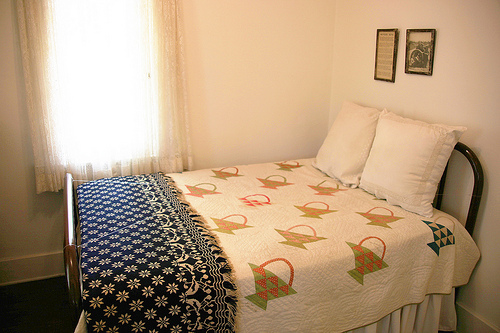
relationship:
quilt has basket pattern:
[163, 165, 463, 309] [270, 223, 334, 258]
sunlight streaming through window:
[48, 2, 152, 163] [8, 1, 198, 174]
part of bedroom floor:
[2, 260, 85, 325] [7, 269, 466, 332]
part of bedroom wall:
[189, 12, 307, 90] [6, 2, 328, 287]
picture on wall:
[401, 26, 432, 76] [333, 6, 498, 326]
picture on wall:
[368, 25, 399, 88] [333, 6, 498, 326]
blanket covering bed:
[65, 167, 227, 326] [57, 71, 478, 325]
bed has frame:
[57, 71, 478, 325] [340, 106, 489, 234]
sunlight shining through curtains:
[48, 2, 152, 163] [15, 2, 197, 189]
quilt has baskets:
[163, 165, 463, 309] [211, 165, 349, 270]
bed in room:
[57, 71, 478, 325] [4, 1, 500, 333]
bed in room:
[57, 71, 478, 325] [4, 1, 490, 324]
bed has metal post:
[57, 71, 478, 325] [367, 119, 481, 213]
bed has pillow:
[57, 71, 478, 325] [366, 111, 448, 205]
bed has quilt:
[57, 71, 478, 325] [163, 165, 463, 309]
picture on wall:
[373, 28, 400, 84] [333, 6, 498, 326]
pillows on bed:
[308, 97, 458, 219] [57, 71, 478, 325]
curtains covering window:
[15, 2, 197, 189] [8, 1, 198, 174]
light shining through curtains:
[48, 2, 152, 163] [15, 2, 197, 189]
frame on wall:
[368, 25, 399, 88] [333, 6, 498, 326]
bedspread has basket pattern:
[163, 165, 463, 309] [273, 224, 328, 250]